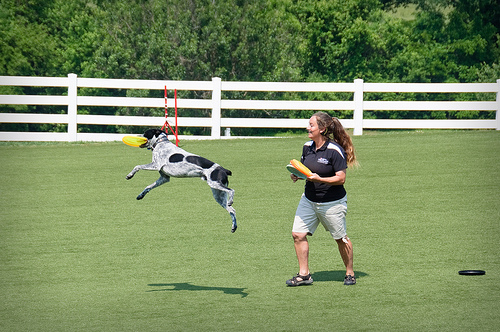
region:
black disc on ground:
[443, 251, 482, 255]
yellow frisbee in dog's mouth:
[107, 125, 174, 141]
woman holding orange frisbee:
[285, 151, 322, 188]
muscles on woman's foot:
[288, 240, 345, 256]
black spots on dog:
[157, 152, 197, 171]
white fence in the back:
[54, 50, 476, 162]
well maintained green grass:
[40, 239, 156, 300]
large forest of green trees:
[101, 10, 413, 93]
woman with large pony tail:
[318, 95, 371, 179]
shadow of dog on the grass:
[131, 255, 271, 300]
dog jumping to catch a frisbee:
[106, 109, 247, 242]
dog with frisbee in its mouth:
[110, 106, 177, 185]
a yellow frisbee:
[119, 130, 151, 160]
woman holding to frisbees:
[268, 142, 323, 194]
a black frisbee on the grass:
[438, 250, 498, 312]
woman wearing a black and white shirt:
[291, 136, 360, 201]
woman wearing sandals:
[284, 265, 373, 306]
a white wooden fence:
[10, 61, 471, 123]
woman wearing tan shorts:
[283, 192, 355, 244]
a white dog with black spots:
[153, 132, 238, 209]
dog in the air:
[104, 118, 239, 230]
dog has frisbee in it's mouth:
[110, 108, 170, 161]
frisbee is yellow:
[110, 123, 162, 165]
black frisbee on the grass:
[430, 248, 492, 298]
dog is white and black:
[141, 137, 257, 228]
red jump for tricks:
[152, 80, 189, 142]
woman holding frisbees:
[282, 153, 334, 200]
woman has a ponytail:
[322, 116, 368, 166]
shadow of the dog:
[151, 255, 250, 316]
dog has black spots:
[138, 112, 238, 190]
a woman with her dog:
[107, 63, 386, 304]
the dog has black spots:
[119, 110, 249, 250]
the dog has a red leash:
[114, 71, 193, 175]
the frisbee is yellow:
[109, 121, 158, 158]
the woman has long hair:
[294, 103, 365, 193]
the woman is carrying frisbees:
[272, 107, 367, 193]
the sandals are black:
[274, 251, 379, 296]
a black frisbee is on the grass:
[442, 246, 495, 297]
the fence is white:
[0, 54, 499, 162]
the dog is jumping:
[108, 63, 256, 276]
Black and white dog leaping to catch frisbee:
[123, 125, 238, 231]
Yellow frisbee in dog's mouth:
[120, 130, 150, 150]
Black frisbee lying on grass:
[453, 261, 489, 281]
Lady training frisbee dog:
[282, 110, 357, 285]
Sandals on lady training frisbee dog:
[281, 267, 312, 282]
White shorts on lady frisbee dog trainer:
[291, 191, 351, 236]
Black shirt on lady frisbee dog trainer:
[295, 141, 345, 201]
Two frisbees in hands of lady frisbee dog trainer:
[285, 155, 315, 181]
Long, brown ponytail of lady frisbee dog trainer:
[332, 111, 354, 162]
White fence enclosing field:
[0, 72, 499, 143]